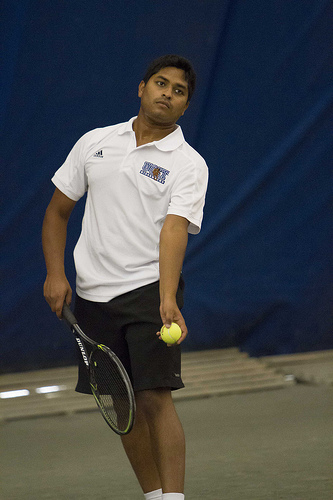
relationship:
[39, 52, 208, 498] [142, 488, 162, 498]
man wearing sock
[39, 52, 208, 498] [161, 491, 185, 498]
man wearing sock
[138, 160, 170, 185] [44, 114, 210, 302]
logo on shirt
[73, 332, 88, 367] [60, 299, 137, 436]
brand on racket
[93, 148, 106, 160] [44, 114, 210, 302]
logo on shirt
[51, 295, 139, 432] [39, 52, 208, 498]
racquet on man